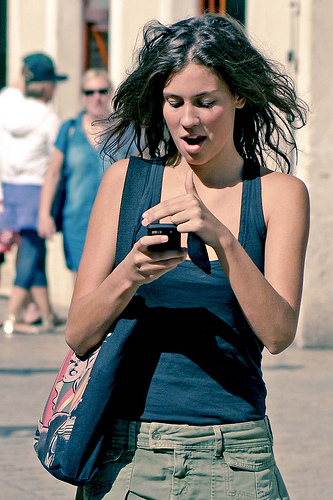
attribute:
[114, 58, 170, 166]
hair — messy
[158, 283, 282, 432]
top — blue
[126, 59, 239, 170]
girl — surprised, suprised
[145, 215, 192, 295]
phone — black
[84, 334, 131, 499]
bag — blue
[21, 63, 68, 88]
cap — green